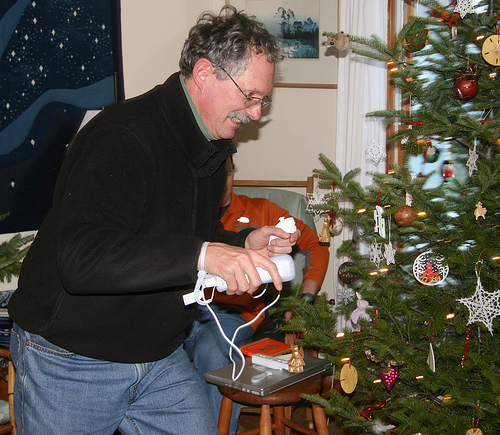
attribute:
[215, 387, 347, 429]
stool — wooden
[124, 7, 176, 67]
wall — white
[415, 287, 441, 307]
leafs — green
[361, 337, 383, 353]
leafs — green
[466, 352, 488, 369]
leafs — green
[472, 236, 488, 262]
leafs — green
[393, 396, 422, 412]
leafs — green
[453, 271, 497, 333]
snowflake ornament — white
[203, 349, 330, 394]
laptop — silver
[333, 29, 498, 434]
tree — christmas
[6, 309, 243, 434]
jeans — blue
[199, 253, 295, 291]
machine — white, hand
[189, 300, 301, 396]
cord — white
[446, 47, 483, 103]
apple — ornament, red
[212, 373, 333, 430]
stool — wood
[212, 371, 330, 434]
stool — wood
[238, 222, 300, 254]
hand — man's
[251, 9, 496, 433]
tree — christmas